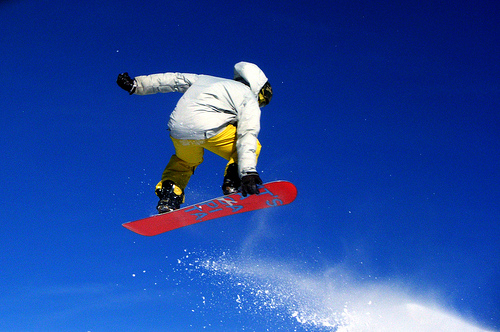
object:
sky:
[2, 0, 500, 330]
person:
[116, 57, 272, 199]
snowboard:
[121, 180, 298, 237]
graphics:
[184, 185, 282, 221]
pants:
[153, 123, 262, 203]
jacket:
[132, 61, 269, 179]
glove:
[242, 172, 263, 197]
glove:
[117, 72, 134, 92]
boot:
[222, 162, 241, 194]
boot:
[155, 179, 183, 213]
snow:
[175, 242, 491, 332]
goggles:
[264, 92, 272, 101]